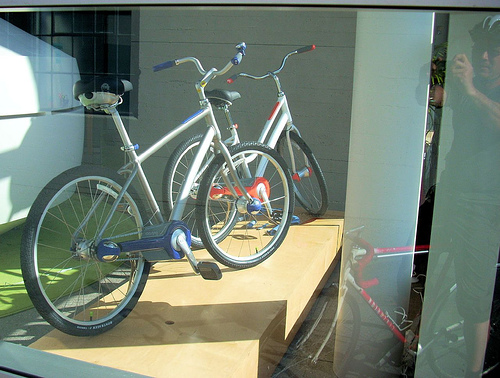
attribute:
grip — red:
[294, 42, 316, 52]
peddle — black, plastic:
[190, 252, 228, 296]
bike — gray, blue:
[8, 30, 297, 344]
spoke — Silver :
[50, 273, 86, 303]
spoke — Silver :
[215, 163, 279, 247]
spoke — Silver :
[38, 182, 140, 322]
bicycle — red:
[163, 45, 334, 250]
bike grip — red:
[296, 40, 316, 55]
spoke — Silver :
[67, 207, 99, 245]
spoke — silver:
[51, 214, 92, 238]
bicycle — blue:
[45, 55, 394, 335]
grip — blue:
[151, 57, 178, 76]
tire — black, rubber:
[22, 170, 154, 330]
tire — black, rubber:
[193, 134, 297, 271]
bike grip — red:
[343, 235, 386, 297]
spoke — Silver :
[76, 185, 91, 220]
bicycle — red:
[333, 219, 417, 355]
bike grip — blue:
[150, 57, 180, 78]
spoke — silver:
[256, 164, 279, 202]